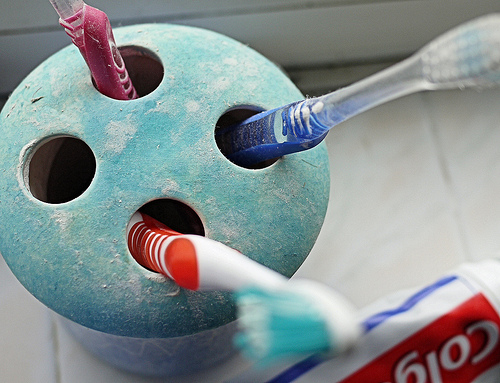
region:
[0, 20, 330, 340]
Green ceramic toothbrush holder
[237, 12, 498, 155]
A blue colored toothbrush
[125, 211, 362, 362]
Red and white toothbrush with green bristles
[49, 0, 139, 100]
Maroon colored toothbrush handle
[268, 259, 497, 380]
Colgate toothpaste tube in red and white and blue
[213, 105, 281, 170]
The hole on the toothbrush stand to stand the blue brush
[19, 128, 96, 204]
A hole in the stand that stands no brush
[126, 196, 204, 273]
The slot standing red brush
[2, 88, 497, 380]
The wall behind the toothbrushes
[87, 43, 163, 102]
The slot that stands maroon brush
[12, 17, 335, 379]
a toothbrush holder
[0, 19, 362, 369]
the toothbrush holder is blue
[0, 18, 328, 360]
toothbrush holder is dusty and old looking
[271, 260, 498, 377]
toothpaste next to the toothbrushes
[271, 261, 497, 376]
the specific toothpaste is colgate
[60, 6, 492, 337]
the toothbrush amount is three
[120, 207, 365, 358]
a red color toothbrush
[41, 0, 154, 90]
a purple color toothbrush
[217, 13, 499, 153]
a blue color toothbrush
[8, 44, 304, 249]
holes in the toothbrush holder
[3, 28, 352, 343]
Light blue toothbrush holder on counter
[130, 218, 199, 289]
Red stripes on white toothbrush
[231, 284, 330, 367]
Blue and white toothbrush bristles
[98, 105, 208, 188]
Residue on toothbrush holder's lid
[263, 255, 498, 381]
Toothpaste tube lying on counter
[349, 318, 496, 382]
Brand name on side of toothpaste tube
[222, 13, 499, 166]
Blue and clear plastic toothbrush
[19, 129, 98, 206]
Hole in toothbrush lid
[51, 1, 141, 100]
Magenta and clear plastic toothbrush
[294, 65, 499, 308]
White tile on bathroom counter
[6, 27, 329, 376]
the toothbrush holder is green in color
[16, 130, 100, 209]
the holder has a hole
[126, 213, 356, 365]
a toothbrush is on the holder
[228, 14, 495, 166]
a toothbrush is on the holder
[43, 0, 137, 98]
a toothbrush is on the holder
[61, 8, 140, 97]
the toothbrush has a red handle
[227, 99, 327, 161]
the toothbrush has a blue handle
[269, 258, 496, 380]
the toothpaste is on the tile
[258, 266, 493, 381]
the toothpaste is white red and blue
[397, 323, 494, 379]
the toothpaste has lettering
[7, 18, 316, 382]
Green toothbrush holder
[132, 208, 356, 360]
Orange and white toothbrush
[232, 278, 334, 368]
Toothbrush with blue and white bristles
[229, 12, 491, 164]
Clear and blue toothbrush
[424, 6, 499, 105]
Blue and white bristles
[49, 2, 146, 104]
Purple and clear toothbrush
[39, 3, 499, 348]
Group of three toothbrushes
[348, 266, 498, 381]
Colgate toothpase tube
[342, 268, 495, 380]
Red, white and blue toothpaste tube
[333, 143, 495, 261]
White countertop